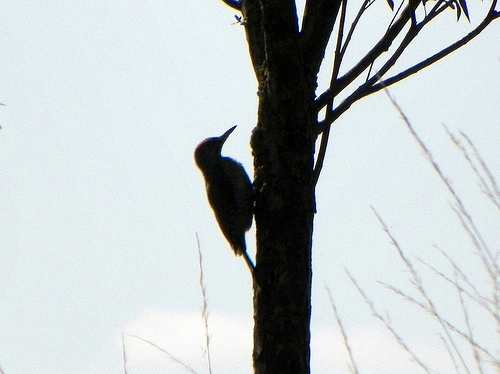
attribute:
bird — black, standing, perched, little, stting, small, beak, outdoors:
[193, 124, 268, 257]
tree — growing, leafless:
[223, 0, 499, 372]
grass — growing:
[119, 71, 498, 373]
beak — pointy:
[219, 124, 238, 144]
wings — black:
[206, 180, 249, 259]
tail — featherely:
[227, 238, 249, 257]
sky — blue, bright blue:
[2, 2, 499, 373]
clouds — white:
[115, 301, 466, 373]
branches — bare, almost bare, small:
[225, 1, 500, 177]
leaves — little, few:
[386, 0, 471, 24]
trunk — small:
[253, 180, 315, 373]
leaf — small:
[387, 0, 398, 12]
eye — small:
[215, 144, 223, 158]